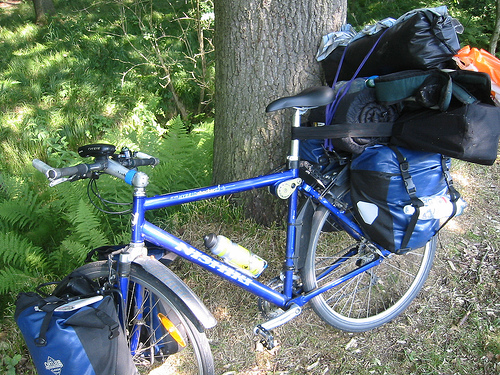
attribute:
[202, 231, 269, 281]
water bottle — plastic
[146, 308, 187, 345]
reflector — orange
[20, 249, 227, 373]
tire — bike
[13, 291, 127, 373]
bag — blue, black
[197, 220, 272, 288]
bottle — water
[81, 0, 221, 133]
bush — brown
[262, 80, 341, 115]
seat — black, padded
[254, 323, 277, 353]
pedal — black